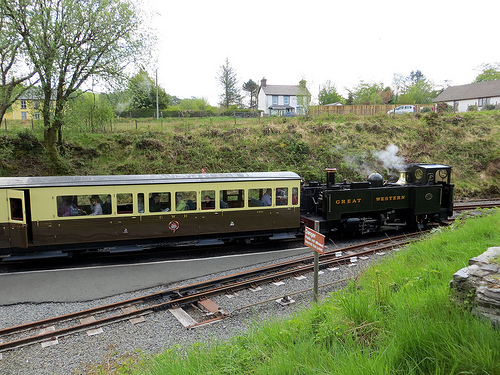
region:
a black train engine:
[302, 165, 452, 231]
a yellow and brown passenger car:
[2, 171, 302, 258]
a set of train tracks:
[0, 231, 429, 355]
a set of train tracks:
[456, 199, 498, 209]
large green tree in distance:
[7, 0, 160, 145]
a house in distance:
[255, 75, 310, 115]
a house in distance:
[434, 77, 499, 109]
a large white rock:
[448, 246, 498, 327]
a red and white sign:
[302, 223, 324, 253]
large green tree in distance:
[216, 57, 243, 113]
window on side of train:
[272, 185, 290, 205]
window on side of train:
[291, 186, 300, 204]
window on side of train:
[223, 188, 248, 210]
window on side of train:
[198, 192, 220, 212]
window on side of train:
[166, 188, 203, 213]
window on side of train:
[149, 195, 171, 210]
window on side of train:
[138, 193, 149, 213]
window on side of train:
[119, 195, 131, 213]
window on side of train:
[51, 195, 115, 215]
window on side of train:
[7, 198, 27, 222]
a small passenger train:
[0, 155, 464, 261]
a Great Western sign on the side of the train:
[332, 195, 409, 205]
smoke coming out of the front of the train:
[334, 138, 410, 180]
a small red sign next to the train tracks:
[303, 217, 327, 302]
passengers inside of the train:
[56, 186, 300, 216]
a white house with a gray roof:
[253, 75, 313, 117]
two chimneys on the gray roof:
[256, 75, 307, 87]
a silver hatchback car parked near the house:
[388, 100, 419, 116]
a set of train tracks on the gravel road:
[0, 191, 498, 353]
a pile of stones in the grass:
[446, 237, 499, 330]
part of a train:
[209, 228, 230, 250]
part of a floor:
[127, 265, 164, 311]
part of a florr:
[98, 268, 130, 298]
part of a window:
[175, 189, 196, 211]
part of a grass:
[412, 326, 434, 350]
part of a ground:
[141, 302, 178, 349]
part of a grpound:
[126, 315, 157, 354]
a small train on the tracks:
[1, 155, 455, 255]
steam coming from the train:
[376, 139, 406, 172]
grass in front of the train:
[79, 209, 499, 373]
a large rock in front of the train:
[450, 243, 498, 326]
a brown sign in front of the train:
[300, 225, 325, 254]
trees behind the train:
[0, 0, 163, 160]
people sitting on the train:
[59, 189, 274, 226]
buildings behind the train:
[0, 81, 497, 118]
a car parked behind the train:
[387, 103, 415, 115]